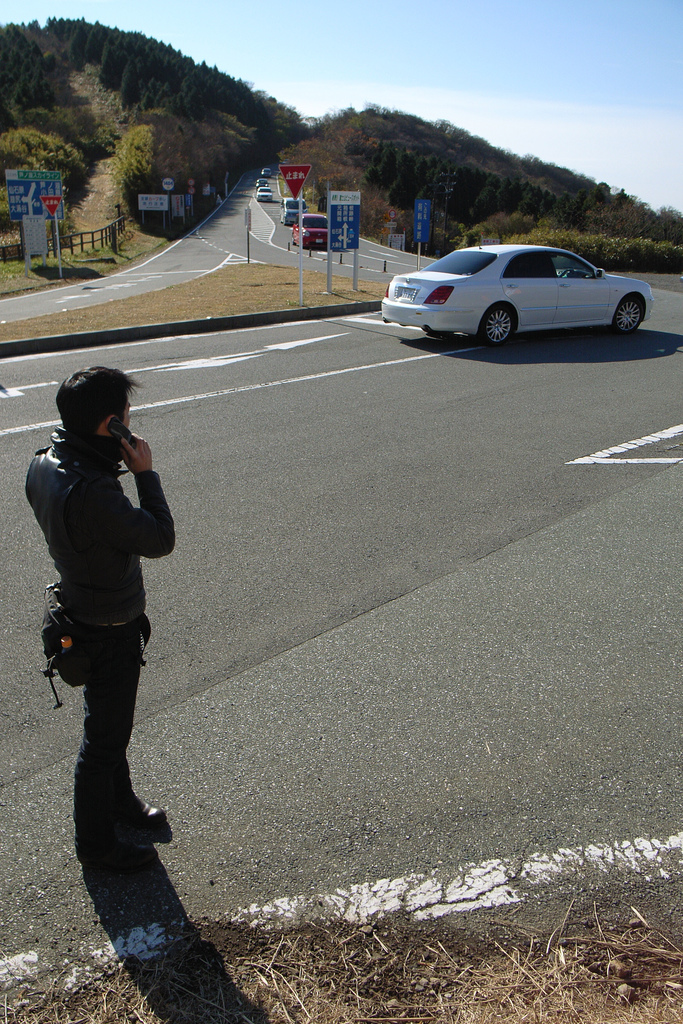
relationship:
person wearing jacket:
[25, 362, 172, 873] [29, 426, 179, 623]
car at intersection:
[379, 243, 655, 346] [3, 233, 682, 981]